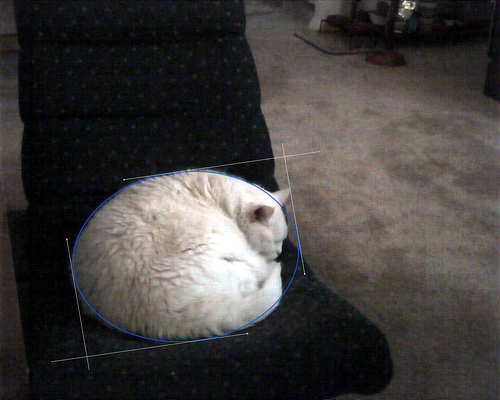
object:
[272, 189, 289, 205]
ear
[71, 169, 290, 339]
cat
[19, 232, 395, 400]
seat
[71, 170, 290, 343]
blue circle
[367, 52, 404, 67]
dish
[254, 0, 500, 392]
ground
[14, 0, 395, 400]
black chair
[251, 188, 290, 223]
ears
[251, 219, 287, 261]
face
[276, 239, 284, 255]
nose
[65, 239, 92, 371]
line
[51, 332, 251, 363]
line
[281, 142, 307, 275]
line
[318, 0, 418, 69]
chair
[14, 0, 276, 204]
pattern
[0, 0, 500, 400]
floor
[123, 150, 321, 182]
line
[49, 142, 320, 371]
lines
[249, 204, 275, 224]
ear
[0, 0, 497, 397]
carpet